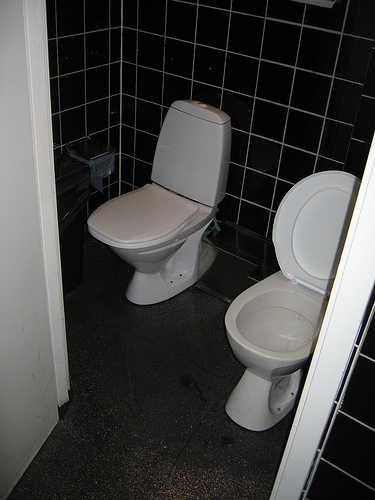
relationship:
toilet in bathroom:
[217, 165, 362, 437] [1, 1, 372, 497]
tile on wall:
[218, 197, 256, 237] [212, 47, 312, 216]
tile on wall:
[243, 167, 283, 205] [137, 54, 346, 240]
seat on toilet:
[268, 167, 362, 296] [217, 165, 362, 437]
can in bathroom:
[39, 155, 107, 269] [83, 128, 265, 299]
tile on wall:
[244, 135, 283, 179] [241, 13, 328, 149]